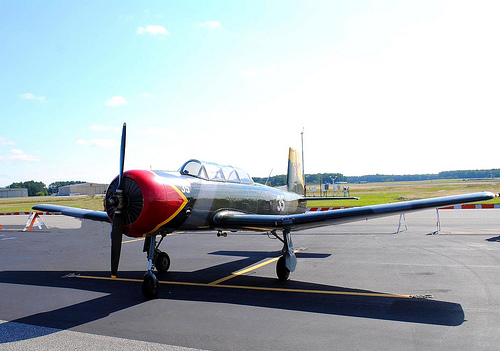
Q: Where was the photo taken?
A: Airport.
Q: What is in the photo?
A: Airplane.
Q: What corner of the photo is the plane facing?
A: Lower left.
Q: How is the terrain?
A: Flat.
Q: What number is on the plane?
A: 35.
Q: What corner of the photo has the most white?
A: Upper right.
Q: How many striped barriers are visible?
A: Three.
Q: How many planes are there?
A: One.